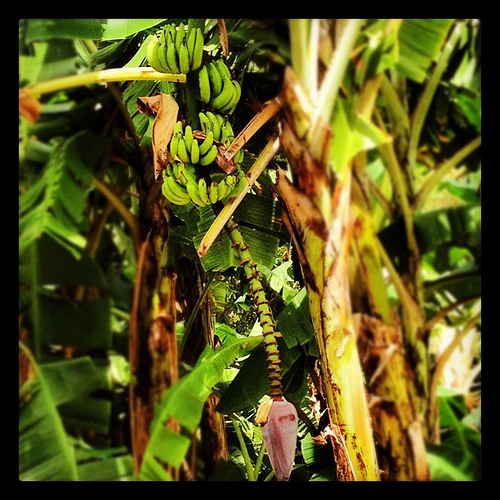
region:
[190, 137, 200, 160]
the banana is green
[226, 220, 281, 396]
a stalk with ridges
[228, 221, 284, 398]
the ridges are brown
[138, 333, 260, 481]
the leaf is green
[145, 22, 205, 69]
a group of bananas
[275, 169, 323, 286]
the piece of plant is brown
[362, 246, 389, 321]
green section of plant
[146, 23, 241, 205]
a bunch of bananas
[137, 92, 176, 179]
dead leaf is hanging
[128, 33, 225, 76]
this is a banana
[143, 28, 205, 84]
the bananas are grees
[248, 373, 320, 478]
this is a flower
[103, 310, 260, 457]
this is a leaf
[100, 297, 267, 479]
the leaf is green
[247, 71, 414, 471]
this is a plant stock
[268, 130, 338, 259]
brown spots on plant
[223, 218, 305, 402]
spiny part of plant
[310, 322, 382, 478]
yellow portion of plant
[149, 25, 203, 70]
BUNCH OF GREEN BANANAS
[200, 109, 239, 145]
BUNCH OF GREEN BANANAS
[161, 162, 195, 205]
BUNCH OF GREEN BANANAS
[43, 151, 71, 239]
GREEN BANANA LEAF ON TREE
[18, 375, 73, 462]
GREEN BANANA LEAF ON TREE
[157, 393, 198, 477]
GREEN BANANA LEAF ON TREE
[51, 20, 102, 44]
GREEN BANANA LEAF ON TREE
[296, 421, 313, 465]
GREEN BANANA LEAF ON TREE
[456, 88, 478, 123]
GREEN BANANA LEAF ON TREE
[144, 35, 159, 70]
banana hangs in tree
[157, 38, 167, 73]
banana hangs in tree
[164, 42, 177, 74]
banana hangs in tree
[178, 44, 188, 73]
banana hangs in tree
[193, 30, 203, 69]
banana hangs in tree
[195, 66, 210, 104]
banana hangs in tree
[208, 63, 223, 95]
banana hangs in tree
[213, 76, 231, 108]
banana hangs in tree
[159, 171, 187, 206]
banana hangs in tree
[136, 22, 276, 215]
A group of bananas on the tree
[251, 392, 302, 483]
The banana flower on the tree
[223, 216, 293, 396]
The stem of the flower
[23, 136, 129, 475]
The leaves are the color green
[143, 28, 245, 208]
The bananas are the color green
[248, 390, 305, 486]
The flower is the color green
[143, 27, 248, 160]
The bananas are not ripe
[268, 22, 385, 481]
The stalk of the tree is the color green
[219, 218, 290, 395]
The bugs on the tree stem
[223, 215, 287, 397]
The bugs are the color brown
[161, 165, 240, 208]
The bananas on the tree are still green.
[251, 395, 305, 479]
The bud on the tree is a pale pink color.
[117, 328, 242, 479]
The long leaf on the tree is green.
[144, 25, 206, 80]
A bunch of bananas on the tree are still not ripe.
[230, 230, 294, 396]
The long stem on the tree is green.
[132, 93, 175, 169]
The leaf next to the bananas is brown in color.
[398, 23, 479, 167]
The long stem on the tree is green.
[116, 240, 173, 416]
The leaf on the tree is brown.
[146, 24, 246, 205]
the bananas are green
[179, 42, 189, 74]
the banana is green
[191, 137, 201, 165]
the banana is green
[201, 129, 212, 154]
the banana is green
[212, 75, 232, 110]
the banana is green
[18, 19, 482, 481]
the banana bunch surrounded by banana trees